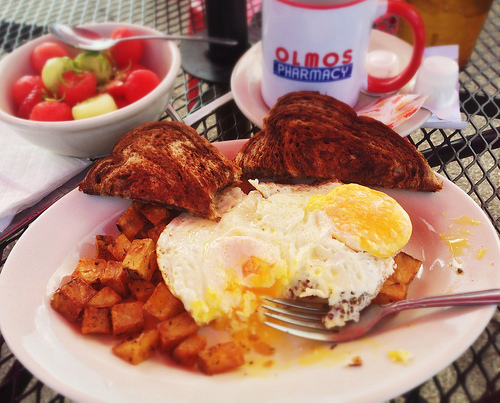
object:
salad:
[13, 25, 149, 125]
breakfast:
[55, 91, 433, 373]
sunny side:
[157, 212, 347, 304]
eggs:
[178, 182, 431, 323]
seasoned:
[69, 226, 205, 358]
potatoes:
[182, 304, 262, 384]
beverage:
[256, 6, 398, 104]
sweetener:
[350, 83, 425, 122]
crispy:
[90, 138, 230, 200]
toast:
[278, 93, 412, 185]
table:
[475, 46, 498, 117]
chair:
[188, 3, 268, 111]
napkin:
[6, 135, 80, 209]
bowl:
[0, 19, 189, 161]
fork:
[276, 290, 498, 324]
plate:
[0, 123, 496, 397]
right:
[303, 279, 494, 300]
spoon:
[48, 12, 247, 52]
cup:
[235, 3, 469, 112]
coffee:
[251, 0, 428, 109]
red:
[374, 2, 435, 94]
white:
[266, 22, 352, 41]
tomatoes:
[20, 59, 77, 122]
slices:
[92, 108, 423, 183]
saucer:
[235, 59, 273, 115]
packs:
[352, 97, 436, 135]